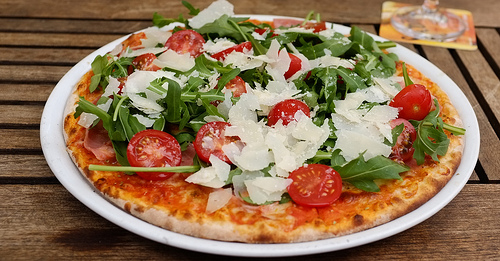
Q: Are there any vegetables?
A: Yes, there are vegetables.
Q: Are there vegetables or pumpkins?
A: Yes, there are vegetables.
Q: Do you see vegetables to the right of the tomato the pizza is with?
A: Yes, there are vegetables to the right of the tomato.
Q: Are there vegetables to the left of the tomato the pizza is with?
A: No, the vegetables are to the right of the tomato.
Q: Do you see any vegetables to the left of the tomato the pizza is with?
A: No, the vegetables are to the right of the tomato.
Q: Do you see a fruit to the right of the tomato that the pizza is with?
A: No, there are vegetables to the right of the tomato.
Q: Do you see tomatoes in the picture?
A: Yes, there is a tomato.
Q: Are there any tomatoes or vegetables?
A: Yes, there is a tomato.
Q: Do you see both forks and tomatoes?
A: No, there is a tomato but no forks.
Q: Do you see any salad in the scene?
A: No, there is no salad.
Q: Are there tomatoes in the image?
A: Yes, there is a tomato.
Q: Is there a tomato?
A: Yes, there is a tomato.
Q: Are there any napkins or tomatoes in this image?
A: Yes, there is a tomato.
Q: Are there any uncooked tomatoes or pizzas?
A: Yes, there is an uncooked tomato.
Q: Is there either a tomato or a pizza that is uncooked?
A: Yes, the tomato is uncooked.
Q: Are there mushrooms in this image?
A: No, there are no mushrooms.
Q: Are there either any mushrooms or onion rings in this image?
A: No, there are no mushrooms or onion rings.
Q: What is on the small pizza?
A: The tomato is on the pizza.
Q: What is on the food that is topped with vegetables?
A: The tomato is on the pizza.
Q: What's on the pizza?
A: The tomato is on the pizza.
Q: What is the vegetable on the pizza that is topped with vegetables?
A: The vegetable is a tomato.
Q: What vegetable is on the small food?
A: The vegetable is a tomato.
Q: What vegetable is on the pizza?
A: The vegetable is a tomato.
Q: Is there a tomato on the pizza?
A: Yes, there is a tomato on the pizza.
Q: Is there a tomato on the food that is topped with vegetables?
A: Yes, there is a tomato on the pizza.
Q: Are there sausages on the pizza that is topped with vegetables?
A: No, there is a tomato on the pizza.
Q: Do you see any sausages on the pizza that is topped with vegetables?
A: No, there is a tomato on the pizza.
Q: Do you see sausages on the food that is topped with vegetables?
A: No, there is a tomato on the pizza.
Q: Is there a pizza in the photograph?
A: Yes, there is a pizza.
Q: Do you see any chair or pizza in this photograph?
A: Yes, there is a pizza.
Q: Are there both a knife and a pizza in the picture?
A: No, there is a pizza but no knives.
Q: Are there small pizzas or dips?
A: Yes, there is a small pizza.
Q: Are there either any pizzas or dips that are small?
A: Yes, the pizza is small.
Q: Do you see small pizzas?
A: Yes, there is a small pizza.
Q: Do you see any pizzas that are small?
A: Yes, there is a pizza that is small.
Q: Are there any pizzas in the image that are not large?
A: Yes, there is a small pizza.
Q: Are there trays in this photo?
A: No, there are no trays.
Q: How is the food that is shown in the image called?
A: The food is a pizza.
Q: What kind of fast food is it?
A: The food is a pizza.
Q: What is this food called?
A: This is a pizza.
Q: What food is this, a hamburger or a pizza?
A: This is a pizza.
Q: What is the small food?
A: The food is a pizza.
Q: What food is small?
A: The food is a pizza.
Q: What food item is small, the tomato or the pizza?
A: The pizza is small.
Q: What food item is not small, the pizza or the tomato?
A: The tomato is not small.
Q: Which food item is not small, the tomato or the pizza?
A: The tomato is not small.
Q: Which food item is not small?
A: The food item is a tomato.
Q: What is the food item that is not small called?
A: The food item is a tomato.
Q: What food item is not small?
A: The food item is a tomato.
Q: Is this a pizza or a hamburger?
A: This is a pizza.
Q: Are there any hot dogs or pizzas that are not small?
A: No, there is a pizza but it is small.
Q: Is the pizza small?
A: Yes, the pizza is small.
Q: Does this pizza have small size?
A: Yes, the pizza is small.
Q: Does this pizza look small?
A: Yes, the pizza is small.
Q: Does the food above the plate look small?
A: Yes, the pizza is small.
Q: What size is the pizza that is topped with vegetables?
A: The pizza is small.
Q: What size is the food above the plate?
A: The pizza is small.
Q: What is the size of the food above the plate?
A: The pizza is small.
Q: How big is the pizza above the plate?
A: The pizza is small.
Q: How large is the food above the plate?
A: The pizza is small.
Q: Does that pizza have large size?
A: No, the pizza is small.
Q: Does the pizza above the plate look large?
A: No, the pizza is small.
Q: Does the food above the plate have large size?
A: No, the pizza is small.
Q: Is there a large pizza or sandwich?
A: No, there is a pizza but it is small.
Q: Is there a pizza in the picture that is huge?
A: No, there is a pizza but it is small.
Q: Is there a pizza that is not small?
A: No, there is a pizza but it is small.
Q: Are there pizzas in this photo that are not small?
A: No, there is a pizza but it is small.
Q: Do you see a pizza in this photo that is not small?
A: No, there is a pizza but it is small.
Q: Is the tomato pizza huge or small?
A: The pizza is small.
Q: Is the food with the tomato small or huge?
A: The pizza is small.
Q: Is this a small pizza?
A: Yes, this is a small pizza.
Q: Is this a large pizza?
A: No, this is a small pizza.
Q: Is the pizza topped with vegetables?
A: Yes, the pizza is topped with vegetables.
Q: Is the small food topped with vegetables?
A: Yes, the pizza is topped with vegetables.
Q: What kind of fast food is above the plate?
A: The food is a pizza.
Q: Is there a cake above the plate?
A: No, there is a pizza above the plate.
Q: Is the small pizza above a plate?
A: Yes, the pizza is above a plate.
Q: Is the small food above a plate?
A: Yes, the pizza is above a plate.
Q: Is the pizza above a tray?
A: No, the pizza is above a plate.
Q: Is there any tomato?
A: Yes, there is a tomato.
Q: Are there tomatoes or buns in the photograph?
A: Yes, there is a tomato.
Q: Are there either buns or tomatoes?
A: Yes, there is a tomato.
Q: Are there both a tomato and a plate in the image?
A: Yes, there are both a tomato and a plate.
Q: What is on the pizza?
A: The tomato is on the pizza.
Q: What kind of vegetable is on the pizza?
A: The vegetable is a tomato.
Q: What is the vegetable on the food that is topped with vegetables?
A: The vegetable is a tomato.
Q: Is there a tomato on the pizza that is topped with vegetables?
A: Yes, there is a tomato on the pizza.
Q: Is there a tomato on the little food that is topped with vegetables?
A: Yes, there is a tomato on the pizza.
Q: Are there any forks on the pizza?
A: No, there is a tomato on the pizza.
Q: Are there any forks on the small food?
A: No, there is a tomato on the pizza.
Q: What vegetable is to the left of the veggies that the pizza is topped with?
A: The vegetable is a tomato.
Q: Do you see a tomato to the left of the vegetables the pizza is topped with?
A: Yes, there is a tomato to the left of the vegetables.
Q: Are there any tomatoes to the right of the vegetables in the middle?
A: No, the tomato is to the left of the veggies.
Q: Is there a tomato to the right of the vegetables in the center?
A: No, the tomato is to the left of the veggies.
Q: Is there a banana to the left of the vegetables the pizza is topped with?
A: No, there is a tomato to the left of the veggies.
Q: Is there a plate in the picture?
A: Yes, there is a plate.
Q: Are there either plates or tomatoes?
A: Yes, there is a plate.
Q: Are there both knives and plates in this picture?
A: No, there is a plate but no knives.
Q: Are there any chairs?
A: No, there are no chairs.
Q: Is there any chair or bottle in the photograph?
A: No, there are no chairs or bottles.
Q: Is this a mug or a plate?
A: This is a plate.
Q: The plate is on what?
A: The plate is on the table.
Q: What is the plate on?
A: The plate is on the table.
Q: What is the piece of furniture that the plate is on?
A: The piece of furniture is a table.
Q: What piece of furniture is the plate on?
A: The plate is on the table.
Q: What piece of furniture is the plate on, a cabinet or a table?
A: The plate is on a table.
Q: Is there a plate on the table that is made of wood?
A: Yes, there is a plate on the table.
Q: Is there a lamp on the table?
A: No, there is a plate on the table.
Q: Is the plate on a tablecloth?
A: No, the plate is on a table.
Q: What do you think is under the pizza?
A: The plate is under the pizza.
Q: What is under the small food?
A: The plate is under the pizza.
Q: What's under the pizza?
A: The plate is under the pizza.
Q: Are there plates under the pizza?
A: Yes, there is a plate under the pizza.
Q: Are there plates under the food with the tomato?
A: Yes, there is a plate under the pizza.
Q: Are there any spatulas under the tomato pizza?
A: No, there is a plate under the pizza.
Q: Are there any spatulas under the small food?
A: No, there is a plate under the pizza.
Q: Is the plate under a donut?
A: No, the plate is under the pizza.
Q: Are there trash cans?
A: No, there are no trash cans.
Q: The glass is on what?
A: The glass is on the table.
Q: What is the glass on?
A: The glass is on the table.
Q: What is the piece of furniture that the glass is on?
A: The piece of furniture is a table.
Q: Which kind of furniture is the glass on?
A: The glass is on the table.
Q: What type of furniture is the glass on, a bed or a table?
A: The glass is on a table.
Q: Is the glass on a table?
A: Yes, the glass is on a table.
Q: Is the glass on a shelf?
A: No, the glass is on a table.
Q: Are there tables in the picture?
A: Yes, there is a table.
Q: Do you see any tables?
A: Yes, there is a table.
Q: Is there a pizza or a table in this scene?
A: Yes, there is a table.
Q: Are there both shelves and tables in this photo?
A: No, there is a table but no shelves.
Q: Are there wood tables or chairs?
A: Yes, there is a wood table.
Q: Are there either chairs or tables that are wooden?
A: Yes, the table is wooden.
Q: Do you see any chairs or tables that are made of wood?
A: Yes, the table is made of wood.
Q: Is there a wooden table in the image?
A: Yes, there is a wood table.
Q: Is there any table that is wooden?
A: Yes, there is a wood table.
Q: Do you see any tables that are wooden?
A: Yes, there is a wood table.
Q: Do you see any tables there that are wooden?
A: Yes, there is a table that is wooden.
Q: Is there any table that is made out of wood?
A: Yes, there is a table that is made of wood.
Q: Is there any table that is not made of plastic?
A: Yes, there is a table that is made of wood.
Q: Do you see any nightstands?
A: No, there are no nightstands.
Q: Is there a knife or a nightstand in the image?
A: No, there are no nightstands or knives.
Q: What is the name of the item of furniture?
A: The piece of furniture is a table.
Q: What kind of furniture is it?
A: The piece of furniture is a table.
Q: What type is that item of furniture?
A: This is a table.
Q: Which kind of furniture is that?
A: This is a table.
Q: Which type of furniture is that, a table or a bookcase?
A: This is a table.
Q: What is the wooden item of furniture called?
A: The piece of furniture is a table.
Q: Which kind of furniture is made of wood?
A: The furniture is a table.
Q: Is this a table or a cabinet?
A: This is a table.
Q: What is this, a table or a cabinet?
A: This is a table.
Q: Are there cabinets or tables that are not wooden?
A: No, there is a table but it is wooden.